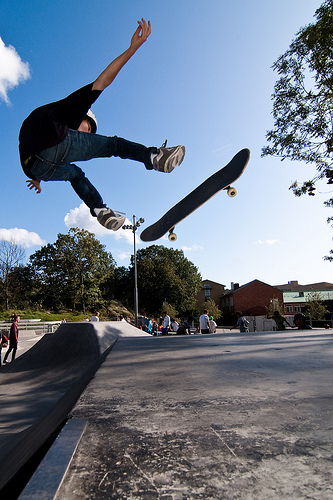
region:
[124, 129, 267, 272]
Black skateboard with white wheels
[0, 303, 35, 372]
Person with red shirt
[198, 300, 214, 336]
Person with white shirt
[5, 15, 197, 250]
Person wearing black shirt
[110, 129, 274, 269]
Wooden skateboard with white wheels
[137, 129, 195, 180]
Grey and white athletic shoe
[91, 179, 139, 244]
Grey and white athletic shoe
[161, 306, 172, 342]
Person wearing white shirt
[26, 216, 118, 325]
Large tree with green leaves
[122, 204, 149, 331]
Large metal pole with lights on top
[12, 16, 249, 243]
skater is in mid-air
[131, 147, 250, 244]
skateboard is in mid-air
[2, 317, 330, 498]
concrete skate park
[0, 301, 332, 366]
people in background watching skaters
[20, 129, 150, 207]
skater wearing blue jeans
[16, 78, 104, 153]
skater wearing black shirt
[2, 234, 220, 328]
green trees in background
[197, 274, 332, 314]
houses in background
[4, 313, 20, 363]
teen wearing red shirt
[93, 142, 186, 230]
skater wearing grey skate shoes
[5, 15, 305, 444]
A picture of a person skateboarding.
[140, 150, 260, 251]
A skateboard with white wheels.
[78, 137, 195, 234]
A pair of grey and white tennis shoes.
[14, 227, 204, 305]
Trees in the background.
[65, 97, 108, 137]
A white safety helmet.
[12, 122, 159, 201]
A pair of blue jeans.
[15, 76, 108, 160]
A short sleeve dark tee shirt.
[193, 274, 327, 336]
Buildings in the bacground.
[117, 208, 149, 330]
A tall street light.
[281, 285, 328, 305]
A light colored roof on a building.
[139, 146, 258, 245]
Skateboard in the air.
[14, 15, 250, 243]
Boy and skateboard in the air.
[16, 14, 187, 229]
Boy in the air.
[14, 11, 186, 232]
Boy with arms outstretched.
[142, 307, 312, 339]
People in the distance.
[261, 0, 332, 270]
Green leaves of a tree against the blue sky.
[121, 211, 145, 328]
Light post.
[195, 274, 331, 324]
Brick homes.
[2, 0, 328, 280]
Blue sky with some puffy white clouds.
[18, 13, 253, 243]
Boy in black shirt and tennis shoes doing tricks on a skateboard.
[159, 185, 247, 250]
the wheels are yellow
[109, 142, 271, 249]
the skateboard is made of wood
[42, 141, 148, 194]
the jeans are green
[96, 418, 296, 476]
the concrete has a black stain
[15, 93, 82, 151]
the top is black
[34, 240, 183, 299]
the trees are green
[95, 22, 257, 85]
the sky is blue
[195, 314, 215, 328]
he has a white top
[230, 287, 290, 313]
the building has a red wall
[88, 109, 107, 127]
the helmet is white